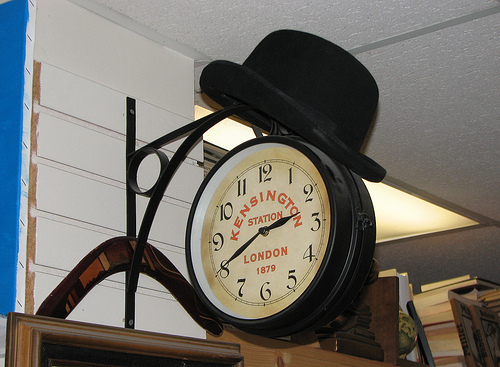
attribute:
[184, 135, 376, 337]
clock — black, cream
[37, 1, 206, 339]
wall — white, wood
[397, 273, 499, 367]
books — arranged, stacked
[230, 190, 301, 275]
letters — red, orange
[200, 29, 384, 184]
hat — black, felt, curved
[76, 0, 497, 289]
ceiling — white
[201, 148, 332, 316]
face — paper, antique, tan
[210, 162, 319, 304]
numbers — black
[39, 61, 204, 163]
panel — white, rectangular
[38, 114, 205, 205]
panel — white, rectangular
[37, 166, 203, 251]
panel — white, rectangular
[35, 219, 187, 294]
panel — white, rectangular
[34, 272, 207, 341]
panel — white, rectangular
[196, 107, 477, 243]
light — yellow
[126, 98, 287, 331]
pole — iron, metal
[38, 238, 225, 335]
boomerang — wood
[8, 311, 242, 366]
frame — brown, wood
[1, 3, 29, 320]
tape — blue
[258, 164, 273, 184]
12 — black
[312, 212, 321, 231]
3 — black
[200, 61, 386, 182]
brim — curled